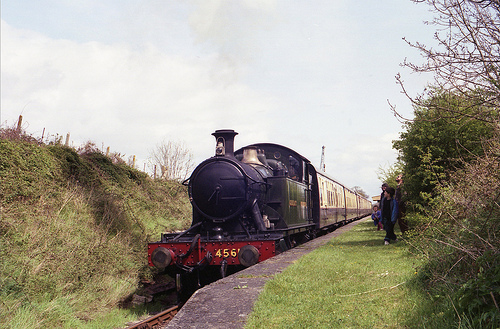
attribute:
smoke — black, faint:
[184, 0, 280, 129]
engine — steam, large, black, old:
[145, 129, 311, 267]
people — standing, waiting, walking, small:
[370, 175, 410, 246]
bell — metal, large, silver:
[214, 135, 228, 156]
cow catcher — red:
[146, 236, 285, 265]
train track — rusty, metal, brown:
[123, 303, 183, 328]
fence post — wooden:
[17, 115, 24, 132]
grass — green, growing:
[1, 206, 449, 328]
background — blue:
[2, 2, 396, 173]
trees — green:
[395, 96, 500, 209]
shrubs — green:
[412, 197, 496, 310]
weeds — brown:
[20, 179, 143, 268]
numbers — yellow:
[215, 248, 246, 258]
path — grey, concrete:
[166, 214, 376, 328]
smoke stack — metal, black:
[212, 129, 238, 156]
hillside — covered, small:
[1, 135, 192, 318]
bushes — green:
[392, 94, 498, 324]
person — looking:
[383, 187, 399, 246]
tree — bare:
[398, 1, 498, 329]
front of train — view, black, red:
[147, 127, 277, 267]